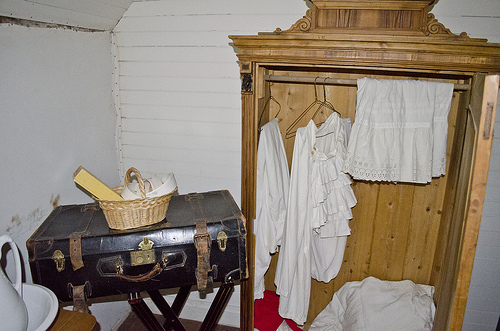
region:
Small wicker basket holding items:
[68, 150, 181, 235]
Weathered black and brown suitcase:
[22, 183, 257, 311]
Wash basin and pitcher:
[0, 220, 79, 329]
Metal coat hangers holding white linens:
[238, 62, 374, 159]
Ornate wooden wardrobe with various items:
[203, 0, 498, 330]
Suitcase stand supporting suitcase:
[36, 245, 256, 329]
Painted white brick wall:
[106, 1, 498, 328]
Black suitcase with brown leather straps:
[26, 190, 259, 312]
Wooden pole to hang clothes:
[243, 65, 484, 107]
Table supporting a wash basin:
[1, 300, 104, 329]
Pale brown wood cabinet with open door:
[226, 3, 498, 328]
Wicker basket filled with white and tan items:
[71, 161, 178, 227]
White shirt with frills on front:
[274, 115, 351, 322]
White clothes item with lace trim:
[343, 75, 457, 187]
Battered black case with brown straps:
[26, 188, 248, 312]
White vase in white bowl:
[3, 232, 57, 329]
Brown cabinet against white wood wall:
[111, 1, 496, 326]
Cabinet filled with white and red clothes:
[228, 1, 495, 328]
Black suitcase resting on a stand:
[24, 188, 246, 328]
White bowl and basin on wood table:
[3, 235, 100, 328]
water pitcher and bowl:
[0, 231, 60, 328]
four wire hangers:
[258, 73, 344, 142]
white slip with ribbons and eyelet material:
[340, 73, 456, 186]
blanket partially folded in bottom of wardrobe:
[305, 274, 437, 329]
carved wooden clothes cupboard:
[226, 0, 498, 329]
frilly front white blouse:
[272, 111, 358, 328]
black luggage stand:
[68, 286, 237, 329]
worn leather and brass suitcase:
[23, 186, 248, 316]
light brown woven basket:
[93, 164, 179, 230]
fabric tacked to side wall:
[1, 18, 134, 329]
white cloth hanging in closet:
[345, 68, 463, 198]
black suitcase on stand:
[16, 153, 282, 329]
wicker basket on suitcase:
[26, 166, 282, 326]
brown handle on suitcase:
[107, 258, 167, 288]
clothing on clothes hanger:
[297, 81, 353, 295]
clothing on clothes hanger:
[263, 76, 290, 286]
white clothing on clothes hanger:
[254, 89, 301, 286]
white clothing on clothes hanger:
[290, 94, 377, 282]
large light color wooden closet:
[231, 51, 487, 326]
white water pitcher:
[0, 221, 59, 325]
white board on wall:
[152, 43, 187, 93]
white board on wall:
[180, 147, 212, 162]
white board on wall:
[171, 6, 196, 61]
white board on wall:
[120, 110, 150, 140]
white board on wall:
[166, 20, 211, 60]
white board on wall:
[117, 40, 148, 75]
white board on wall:
[187, 105, 203, 121]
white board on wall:
[472, 290, 489, 310]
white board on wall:
[165, 136, 195, 156]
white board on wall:
[160, 96, 201, 151]